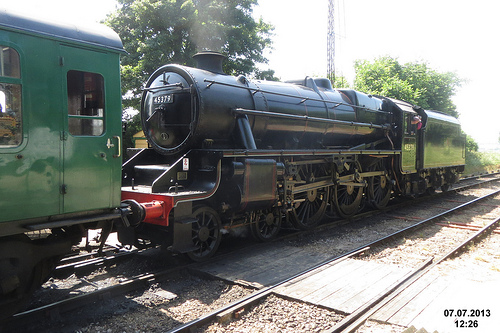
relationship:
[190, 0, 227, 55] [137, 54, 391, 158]
smoke coming out of engine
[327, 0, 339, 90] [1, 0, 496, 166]
radio tower in background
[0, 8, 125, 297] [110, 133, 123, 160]
railroad car has door handle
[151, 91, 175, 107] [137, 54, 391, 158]
number written on engine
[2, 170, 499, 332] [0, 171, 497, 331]
gravel between tracks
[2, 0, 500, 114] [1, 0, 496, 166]
sky in background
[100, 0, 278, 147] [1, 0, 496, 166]
tree in background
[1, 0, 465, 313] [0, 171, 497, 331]
train on top of tracks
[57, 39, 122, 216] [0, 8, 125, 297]
door on side of railroad car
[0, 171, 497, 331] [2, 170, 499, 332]
tracks on top of gravel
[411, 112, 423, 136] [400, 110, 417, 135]
conductor sticking head out of window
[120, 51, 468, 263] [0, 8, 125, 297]
locomotive behind railroad car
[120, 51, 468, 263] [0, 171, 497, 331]
locomotive on tracks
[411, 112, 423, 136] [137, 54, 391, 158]
conductor behind engine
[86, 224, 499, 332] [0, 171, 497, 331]
walkway going over tracks